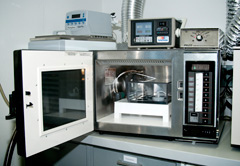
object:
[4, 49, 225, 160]
oven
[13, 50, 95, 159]
door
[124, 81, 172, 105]
container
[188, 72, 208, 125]
buttons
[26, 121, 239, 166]
stand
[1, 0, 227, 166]
wall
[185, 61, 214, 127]
microwave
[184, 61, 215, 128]
control panel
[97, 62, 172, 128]
inside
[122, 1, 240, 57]
tubing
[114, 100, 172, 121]
microwave table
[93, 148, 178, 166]
drawer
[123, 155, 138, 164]
label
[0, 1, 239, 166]
laboratory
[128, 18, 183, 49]
monitoring device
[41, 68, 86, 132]
window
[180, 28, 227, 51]
monitor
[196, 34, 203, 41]
dial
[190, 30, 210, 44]
numbers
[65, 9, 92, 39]
electronic device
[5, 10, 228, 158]
lab equipment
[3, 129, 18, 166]
pipe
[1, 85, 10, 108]
pipe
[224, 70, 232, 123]
power cord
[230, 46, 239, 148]
box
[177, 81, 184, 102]
slots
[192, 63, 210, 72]
display